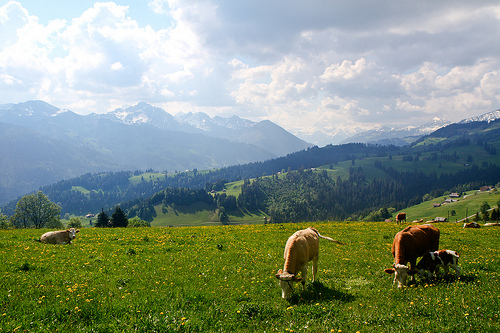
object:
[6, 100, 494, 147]
snow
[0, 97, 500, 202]
mountains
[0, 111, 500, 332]
hill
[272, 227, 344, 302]
cow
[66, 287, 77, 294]
flower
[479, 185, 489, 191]
houses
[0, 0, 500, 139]
sky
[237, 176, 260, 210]
trees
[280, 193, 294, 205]
leaves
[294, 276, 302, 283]
ear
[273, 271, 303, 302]
head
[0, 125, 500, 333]
grass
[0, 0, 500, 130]
cloud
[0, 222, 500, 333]
ground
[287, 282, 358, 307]
shadow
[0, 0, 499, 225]
background